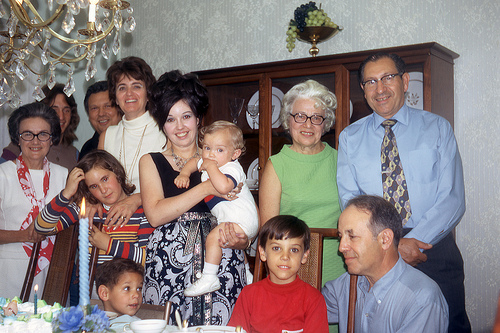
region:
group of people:
[12, 55, 464, 331]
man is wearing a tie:
[332, 54, 452, 201]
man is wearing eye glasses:
[343, 56, 460, 228]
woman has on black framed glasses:
[273, 74, 340, 154]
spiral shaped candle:
[66, 199, 105, 320]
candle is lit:
[76, 200, 101, 313]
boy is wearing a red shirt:
[235, 214, 340, 331]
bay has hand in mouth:
[193, 125, 243, 173]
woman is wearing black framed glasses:
[11, 111, 66, 163]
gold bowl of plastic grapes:
[274, 3, 354, 59]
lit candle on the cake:
[22, 282, 42, 314]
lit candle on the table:
[61, 174, 102, 321]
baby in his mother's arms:
[147, 97, 257, 282]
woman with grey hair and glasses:
[277, 76, 347, 198]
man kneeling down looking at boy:
[326, 194, 426, 321]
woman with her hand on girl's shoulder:
[91, 48, 150, 239]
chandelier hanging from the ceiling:
[4, 3, 133, 108]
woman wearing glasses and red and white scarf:
[4, 108, 70, 225]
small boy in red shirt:
[242, 218, 327, 325]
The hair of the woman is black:
[148, 68, 211, 121]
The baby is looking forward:
[192, 121, 244, 192]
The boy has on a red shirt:
[233, 279, 332, 329]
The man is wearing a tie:
[348, 78, 434, 226]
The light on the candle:
[68, 190, 96, 227]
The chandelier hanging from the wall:
[4, 6, 139, 118]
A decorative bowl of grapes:
[275, 2, 362, 60]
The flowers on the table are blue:
[54, 302, 113, 332]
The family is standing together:
[2, 31, 466, 331]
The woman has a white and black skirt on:
[142, 211, 251, 326]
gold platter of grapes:
[285, 2, 343, 52]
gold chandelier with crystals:
[2, 4, 124, 60]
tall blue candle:
[78, 199, 91, 306]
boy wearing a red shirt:
[251, 217, 325, 324]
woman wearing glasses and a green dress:
[284, 82, 336, 220]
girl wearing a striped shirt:
[76, 148, 149, 255]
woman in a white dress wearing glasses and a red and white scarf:
[8, 103, 60, 194]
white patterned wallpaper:
[134, 5, 261, 57]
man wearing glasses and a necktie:
[352, 54, 459, 192]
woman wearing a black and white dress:
[148, 75, 243, 307]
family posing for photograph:
[3, 10, 479, 325]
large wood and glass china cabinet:
[170, 37, 465, 172]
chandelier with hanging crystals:
[1, 0, 136, 105]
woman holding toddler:
[136, 65, 256, 325]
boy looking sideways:
[82, 255, 142, 315]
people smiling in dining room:
[11, 51, 192, 152]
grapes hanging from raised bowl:
[282, 1, 337, 56]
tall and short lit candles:
[28, 195, 94, 327]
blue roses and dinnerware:
[50, 296, 250, 328]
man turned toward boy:
[231, 192, 451, 327]